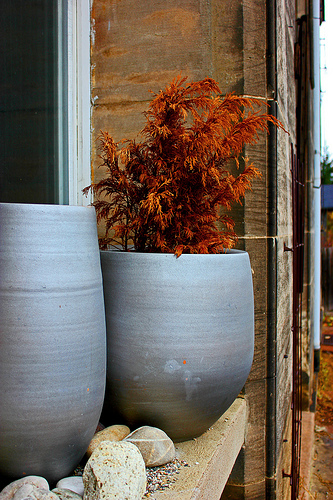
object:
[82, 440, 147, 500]
rock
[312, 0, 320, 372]
pipe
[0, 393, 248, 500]
ledge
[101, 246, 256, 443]
planter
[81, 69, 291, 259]
bush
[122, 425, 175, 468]
stone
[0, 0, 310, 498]
building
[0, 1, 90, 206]
window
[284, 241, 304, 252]
nail